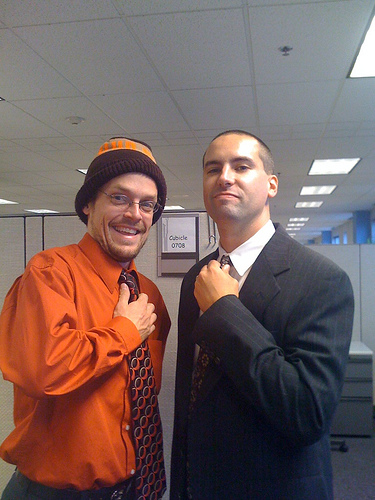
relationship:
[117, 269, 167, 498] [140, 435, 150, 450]
tie with circle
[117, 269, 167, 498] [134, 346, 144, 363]
tie with circle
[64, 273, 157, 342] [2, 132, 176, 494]
hand of man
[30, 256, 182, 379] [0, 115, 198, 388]
arm of man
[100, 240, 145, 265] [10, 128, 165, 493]
chin of man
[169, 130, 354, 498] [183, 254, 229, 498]
business man adjusting tie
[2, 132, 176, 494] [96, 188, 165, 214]
man wearing glasses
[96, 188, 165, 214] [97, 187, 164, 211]
glasses with frame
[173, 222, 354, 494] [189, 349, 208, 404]
suit and tie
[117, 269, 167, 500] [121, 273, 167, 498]
tie with circles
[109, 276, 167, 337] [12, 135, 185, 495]
fingers on man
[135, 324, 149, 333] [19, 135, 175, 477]
veins on man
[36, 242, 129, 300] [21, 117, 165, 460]
shoulder on man